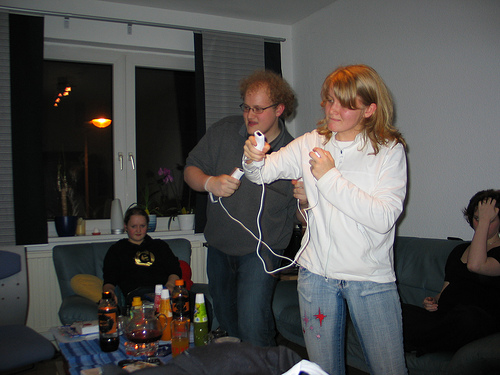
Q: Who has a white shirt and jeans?
A: The woman playing a game.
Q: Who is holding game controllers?
A: The man with glasses and the blonde woman.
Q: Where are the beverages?
A: On a coffee table.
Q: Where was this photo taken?
A: In a living room.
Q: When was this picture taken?
A: At nighttime.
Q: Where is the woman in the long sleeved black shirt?
A: Near the window.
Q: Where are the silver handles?
A: On the windows.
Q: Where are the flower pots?
A: On the windowsill.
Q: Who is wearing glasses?
A: The man in the gray shirt.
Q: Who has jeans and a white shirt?
A: The woman playing the game.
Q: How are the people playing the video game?
A: Standing on the floor.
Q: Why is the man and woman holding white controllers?
A: To play a Wii game.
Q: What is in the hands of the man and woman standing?
A: White Wii controls.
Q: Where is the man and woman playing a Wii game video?
A: Living room of an apartment.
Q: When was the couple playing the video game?
A: Late on a Saturday night.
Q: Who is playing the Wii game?
A: A woman and man.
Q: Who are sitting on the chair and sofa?
A: Two women in black.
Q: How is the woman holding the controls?
A: In both hands.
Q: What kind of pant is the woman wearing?
A: Blue jeans.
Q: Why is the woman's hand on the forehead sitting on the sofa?
A: Tired of watching the couple play a video game.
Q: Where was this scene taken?
A: Living room.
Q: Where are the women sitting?
A: On the blue sofa.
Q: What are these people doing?
A: Playing Wii.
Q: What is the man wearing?
A: Blue jeans.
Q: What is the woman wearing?
A: White top and jeans.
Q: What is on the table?
A: Soda bottles.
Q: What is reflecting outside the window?
A: Street lights.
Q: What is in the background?
A: Windows.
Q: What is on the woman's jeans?
A: Red stars.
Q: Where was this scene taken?
A: It is an indoor scene.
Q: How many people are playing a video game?
A: Two.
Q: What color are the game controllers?
A: White.